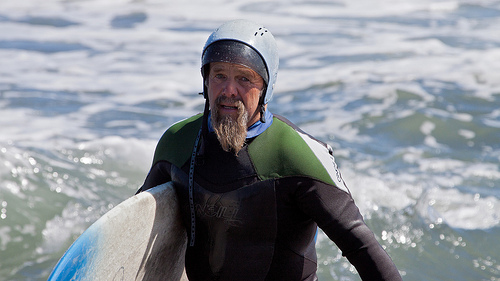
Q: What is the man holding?
A: A surfboard.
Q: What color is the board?
A: Blue and white.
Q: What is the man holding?
A: Surfboard.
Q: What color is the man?
A: White.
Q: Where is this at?
A: Ocean.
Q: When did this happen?
A: During the day time.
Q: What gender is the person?
A: Male.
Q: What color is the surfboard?
A: Blue and white.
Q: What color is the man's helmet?
A: Gray.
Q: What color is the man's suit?
A: Green, white, and black.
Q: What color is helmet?
A: Gray.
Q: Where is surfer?
A: Water.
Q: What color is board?
A: Blue and white.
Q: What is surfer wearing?
A: Suit.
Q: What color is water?
A: Blue and green.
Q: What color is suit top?
A: Green.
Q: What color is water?
A: Blue and green.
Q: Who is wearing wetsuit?
A: A man.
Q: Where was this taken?
A: Ocean.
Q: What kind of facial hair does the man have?
A: Mustache and beard.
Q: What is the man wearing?
A: Wetsuit.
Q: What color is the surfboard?
A: White and blue.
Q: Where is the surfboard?
A: Under the man's arm.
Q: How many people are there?
A: 1.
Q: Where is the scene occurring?
A: At the ocean.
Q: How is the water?
A: Choppy.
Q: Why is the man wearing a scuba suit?
A: To keep warm.